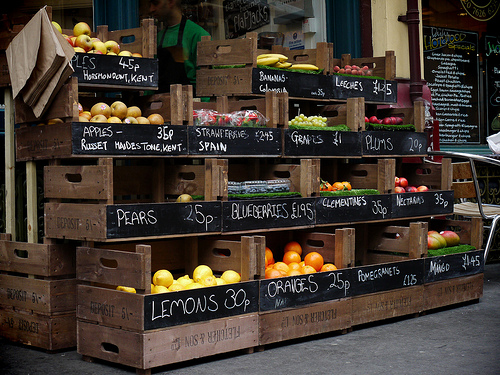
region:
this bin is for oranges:
[253, 240, 340, 329]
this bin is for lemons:
[73, 242, 239, 363]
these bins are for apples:
[0, 8, 175, 153]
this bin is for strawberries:
[181, 81, 274, 153]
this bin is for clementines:
[312, 156, 384, 218]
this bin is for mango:
[423, 225, 479, 267]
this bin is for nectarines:
[386, 153, 458, 218]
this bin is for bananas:
[191, 35, 324, 102]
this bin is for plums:
[360, 109, 432, 169]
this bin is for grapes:
[281, 100, 350, 162]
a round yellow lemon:
[151, 269, 172, 289]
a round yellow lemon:
[167, 282, 182, 290]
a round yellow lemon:
[192, 264, 209, 281]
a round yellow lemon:
[219, 267, 239, 283]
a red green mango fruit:
[429, 236, 444, 250]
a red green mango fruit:
[429, 229, 448, 247]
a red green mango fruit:
[439, 229, 459, 246]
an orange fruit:
[303, 250, 323, 270]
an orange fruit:
[283, 249, 302, 264]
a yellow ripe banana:
[255, 54, 278, 65]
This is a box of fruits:
[107, 250, 248, 322]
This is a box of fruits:
[260, 233, 350, 285]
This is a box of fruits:
[404, 218, 483, 263]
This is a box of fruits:
[324, 223, 413, 270]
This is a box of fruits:
[87, 153, 209, 213]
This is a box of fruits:
[210, 159, 312, 216]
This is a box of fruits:
[289, 149, 375, 201]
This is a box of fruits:
[372, 158, 442, 203]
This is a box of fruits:
[61, 74, 168, 147]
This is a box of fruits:
[178, 77, 280, 147]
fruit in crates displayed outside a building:
[3, 3, 487, 369]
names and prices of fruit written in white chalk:
[73, 52, 484, 327]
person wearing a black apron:
[153, 1, 208, 87]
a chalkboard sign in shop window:
[418, 1, 498, 145]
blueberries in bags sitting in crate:
[223, 156, 317, 225]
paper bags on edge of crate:
[5, 5, 153, 121]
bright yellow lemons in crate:
[73, 236, 258, 371]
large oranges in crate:
[256, 224, 351, 343]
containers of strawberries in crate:
[185, 86, 279, 160]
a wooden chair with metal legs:
[448, 156, 498, 263]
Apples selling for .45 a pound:
[41, 3, 170, 90]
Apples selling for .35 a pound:
[71, 90, 181, 151]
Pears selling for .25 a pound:
[95, 155, 220, 237]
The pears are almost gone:
[96, 155, 221, 226]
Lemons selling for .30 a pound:
[112, 237, 252, 322]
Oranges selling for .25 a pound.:
[260, 225, 346, 306]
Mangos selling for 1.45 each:
[416, 210, 488, 300]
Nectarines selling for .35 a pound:
[385, 147, 465, 212]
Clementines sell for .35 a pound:
[310, 150, 390, 225]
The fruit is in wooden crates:
[20, 3, 488, 348]